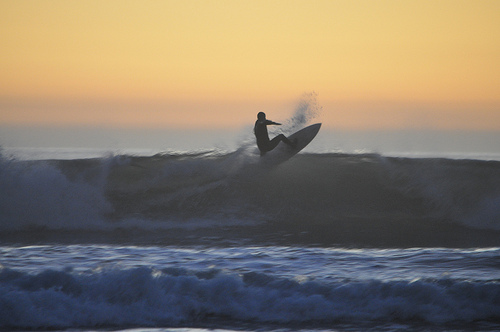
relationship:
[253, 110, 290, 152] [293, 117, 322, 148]
man riding surfboard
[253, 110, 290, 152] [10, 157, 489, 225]
man riding wave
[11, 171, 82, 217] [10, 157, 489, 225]
foam floating on wave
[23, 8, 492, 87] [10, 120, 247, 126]
sunset above horizon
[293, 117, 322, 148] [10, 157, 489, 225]
surfboard riding wave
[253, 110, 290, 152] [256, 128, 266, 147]
man wearing wetsuit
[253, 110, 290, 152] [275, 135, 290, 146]
man has leg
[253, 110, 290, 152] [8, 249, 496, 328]
man in ocean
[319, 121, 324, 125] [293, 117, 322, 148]
tip of surfboard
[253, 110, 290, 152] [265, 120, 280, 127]
man extending arm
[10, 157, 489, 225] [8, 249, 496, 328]
wave inside of ocean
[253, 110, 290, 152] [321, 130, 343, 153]
man rising into air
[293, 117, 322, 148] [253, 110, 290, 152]
surfboard below man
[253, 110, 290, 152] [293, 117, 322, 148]
man riding on surfboard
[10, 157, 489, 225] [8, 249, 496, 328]
wave forming in ocean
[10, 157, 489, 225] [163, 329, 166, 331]
wave near shore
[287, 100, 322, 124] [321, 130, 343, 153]
water spraying into air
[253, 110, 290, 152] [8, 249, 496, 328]
man surfing in ocean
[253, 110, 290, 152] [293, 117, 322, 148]
man crouched on surfboard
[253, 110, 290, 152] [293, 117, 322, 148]
man balancing on surfboard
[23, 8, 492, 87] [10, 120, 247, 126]
sunset over horizon